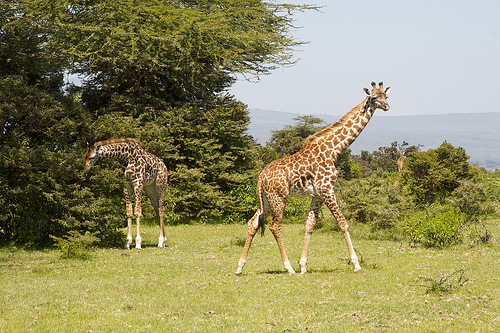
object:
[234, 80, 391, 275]
giraffe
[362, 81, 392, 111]
head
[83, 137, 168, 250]
giraffe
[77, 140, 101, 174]
head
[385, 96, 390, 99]
eyes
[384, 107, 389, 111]
mouth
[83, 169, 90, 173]
mouth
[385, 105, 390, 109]
nose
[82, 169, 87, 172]
nose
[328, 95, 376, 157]
neck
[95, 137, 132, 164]
neck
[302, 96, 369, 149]
mane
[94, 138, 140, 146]
mane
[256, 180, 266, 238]
tail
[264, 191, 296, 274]
legs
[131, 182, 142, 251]
legs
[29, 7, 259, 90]
leaves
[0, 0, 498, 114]
sky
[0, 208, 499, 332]
field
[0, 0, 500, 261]
bush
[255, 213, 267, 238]
hair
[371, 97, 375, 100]
eye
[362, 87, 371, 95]
ears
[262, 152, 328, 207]
body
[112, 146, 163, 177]
body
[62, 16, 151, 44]
branch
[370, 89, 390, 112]
face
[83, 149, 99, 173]
face